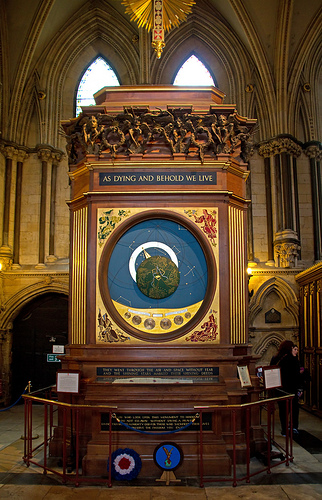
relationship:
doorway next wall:
[5, 273, 82, 446] [69, 237, 307, 382]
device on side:
[89, 197, 237, 349] [84, 186, 245, 363]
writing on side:
[96, 364, 225, 384] [45, 338, 294, 494]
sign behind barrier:
[52, 363, 94, 399] [17, 382, 302, 487]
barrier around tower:
[17, 382, 302, 487] [43, 67, 299, 482]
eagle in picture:
[158, 446, 177, 470] [150, 440, 183, 477]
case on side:
[286, 259, 311, 431] [259, 176, 311, 462]